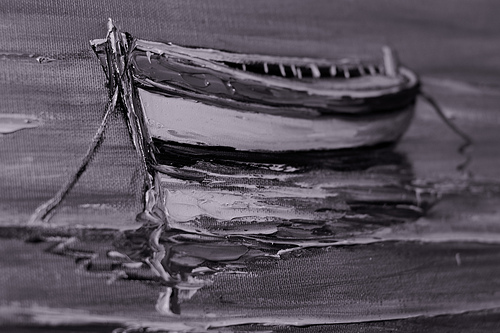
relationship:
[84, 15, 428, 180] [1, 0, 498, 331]
boat painted on canvas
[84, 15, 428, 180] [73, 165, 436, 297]
boat in water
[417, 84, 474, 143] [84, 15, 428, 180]
rope at boat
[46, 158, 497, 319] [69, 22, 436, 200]
water carries boat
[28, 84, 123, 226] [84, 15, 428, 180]
rope on boat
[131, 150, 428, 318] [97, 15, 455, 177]
boat shadow of boat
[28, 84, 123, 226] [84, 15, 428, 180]
rope attached to front of boat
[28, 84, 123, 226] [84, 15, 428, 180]
rope attached to back of boat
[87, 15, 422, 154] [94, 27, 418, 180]
boat of boat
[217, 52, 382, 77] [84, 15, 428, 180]
cabin on boat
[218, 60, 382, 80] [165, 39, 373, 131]
cabin on cabin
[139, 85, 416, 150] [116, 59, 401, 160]
stripe on hull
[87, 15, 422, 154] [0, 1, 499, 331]
boat sitting in water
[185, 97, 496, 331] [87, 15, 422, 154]
painting of boat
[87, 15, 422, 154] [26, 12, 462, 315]
boat on water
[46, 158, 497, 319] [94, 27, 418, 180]
water around boat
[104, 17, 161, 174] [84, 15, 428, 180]
part of boat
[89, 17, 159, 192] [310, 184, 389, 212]
post in water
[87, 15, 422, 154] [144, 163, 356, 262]
boat in water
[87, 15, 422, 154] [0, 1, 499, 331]
boat in water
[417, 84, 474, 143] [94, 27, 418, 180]
rope holding boat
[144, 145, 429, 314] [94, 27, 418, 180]
boat shadow of boat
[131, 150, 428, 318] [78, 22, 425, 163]
boat shadow of boat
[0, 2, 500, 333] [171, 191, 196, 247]
painting of water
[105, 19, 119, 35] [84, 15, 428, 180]
tip of boat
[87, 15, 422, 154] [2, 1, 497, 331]
boat at sea